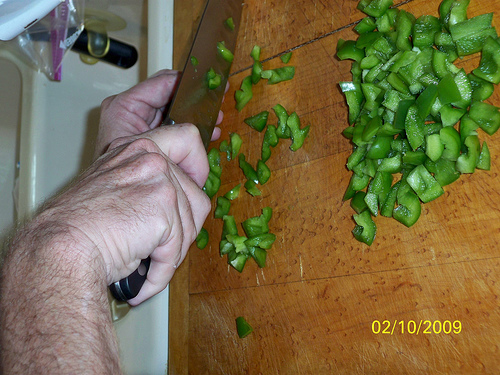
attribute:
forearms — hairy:
[1, 105, 165, 372]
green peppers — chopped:
[328, 4, 498, 241]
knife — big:
[104, 7, 232, 310]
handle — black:
[108, 266, 143, 300]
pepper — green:
[464, 99, 496, 133]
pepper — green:
[435, 74, 472, 109]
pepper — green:
[451, 12, 498, 61]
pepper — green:
[404, 164, 446, 204]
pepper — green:
[390, 186, 425, 226]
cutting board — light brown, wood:
[161, 2, 496, 370]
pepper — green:
[437, 70, 477, 111]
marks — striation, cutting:
[359, 271, 427, 304]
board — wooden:
[163, 0, 498, 374]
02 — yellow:
[370, 317, 391, 334]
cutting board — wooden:
[251, 220, 418, 330]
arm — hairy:
[25, 217, 112, 340]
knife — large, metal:
[161, 0, 243, 154]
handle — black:
[99, 254, 159, 309]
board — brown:
[234, 31, 458, 373]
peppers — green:
[188, 27, 283, 289]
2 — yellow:
[423, 318, 432, 335]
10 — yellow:
[398, 319, 418, 336]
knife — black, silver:
[162, 1, 240, 144]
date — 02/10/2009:
[371, 297, 468, 344]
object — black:
[25, 24, 146, 74]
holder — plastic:
[49, 4, 131, 71]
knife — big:
[89, 17, 306, 303]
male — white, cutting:
[7, 66, 222, 374]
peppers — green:
[318, 3, 496, 245]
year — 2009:
[423, 318, 463, 335]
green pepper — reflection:
[332, 1, 498, 246]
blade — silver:
[165, 0, 243, 153]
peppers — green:
[344, 24, 492, 196]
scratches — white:
[296, 256, 305, 286]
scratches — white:
[252, 267, 268, 284]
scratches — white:
[224, 263, 231, 273]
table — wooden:
[169, 1, 499, 373]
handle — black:
[110, 116, 188, 299]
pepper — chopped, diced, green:
[352, 210, 377, 245]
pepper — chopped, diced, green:
[402, 163, 444, 202]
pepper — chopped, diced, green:
[401, 100, 425, 147]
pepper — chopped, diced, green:
[334, 38, 364, 62]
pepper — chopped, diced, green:
[450, 61, 470, 105]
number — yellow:
[369, 318, 381, 335]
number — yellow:
[380, 317, 391, 333]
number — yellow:
[396, 320, 405, 335]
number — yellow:
[404, 317, 416, 335]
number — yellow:
[422, 319, 432, 334]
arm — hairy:
[0, 219, 130, 373]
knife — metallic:
[105, 1, 245, 301]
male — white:
[2, 65, 214, 355]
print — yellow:
[361, 306, 484, 345]